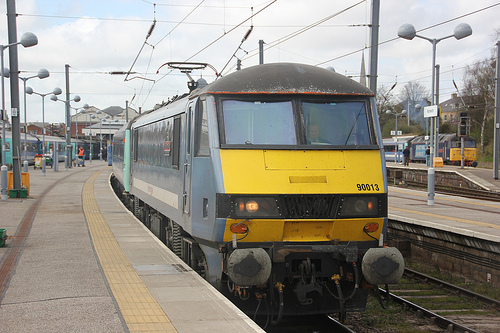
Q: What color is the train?
A: Yellow and blue.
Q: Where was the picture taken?
A: At a train station.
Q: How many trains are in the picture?
A: 2.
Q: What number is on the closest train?
A: 90013.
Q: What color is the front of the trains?
A: Yellow.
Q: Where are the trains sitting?
A: On tracks.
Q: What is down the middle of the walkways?
A: Light poles.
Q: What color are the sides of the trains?
A: Blue.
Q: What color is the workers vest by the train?
A: Orange.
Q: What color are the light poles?
A: Gray.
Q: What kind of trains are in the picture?
A: Passenger trains.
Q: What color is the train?
A: Gray and yellow.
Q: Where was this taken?
A: Train station.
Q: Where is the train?
A: On the track.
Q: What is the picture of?
A: Train.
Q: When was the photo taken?
A: Daytime.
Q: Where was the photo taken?
A: Train station.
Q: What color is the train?
A: Grey and yellow.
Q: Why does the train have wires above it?
A: Provides electricity.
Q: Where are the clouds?
A: Sky.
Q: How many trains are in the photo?
A: 2.